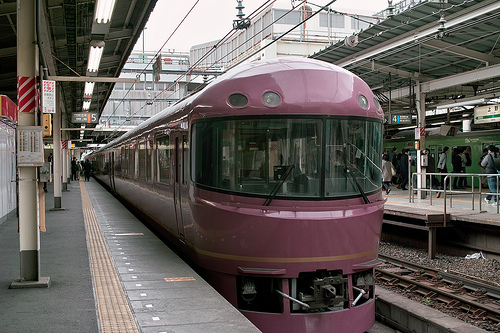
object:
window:
[147, 116, 384, 199]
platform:
[0, 156, 250, 326]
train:
[85, 56, 385, 329]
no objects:
[409, 315, 427, 325]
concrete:
[60, 174, 244, 329]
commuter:
[119, 97, 413, 298]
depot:
[29, 32, 143, 273]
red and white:
[10, 72, 50, 127]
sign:
[11, 71, 68, 122]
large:
[199, 115, 391, 216]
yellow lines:
[76, 183, 134, 331]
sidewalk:
[62, 142, 195, 329]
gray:
[146, 14, 213, 66]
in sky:
[147, 7, 194, 54]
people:
[69, 139, 103, 189]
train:
[387, 113, 498, 193]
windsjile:
[422, 143, 495, 206]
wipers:
[264, 161, 387, 214]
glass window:
[231, 140, 385, 215]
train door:
[142, 104, 214, 234]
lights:
[201, 73, 402, 136]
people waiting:
[60, 148, 119, 188]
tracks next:
[387, 225, 498, 323]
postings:
[23, 49, 59, 186]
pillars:
[47, 21, 84, 253]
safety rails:
[406, 166, 480, 216]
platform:
[382, 154, 500, 241]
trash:
[434, 233, 497, 284]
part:
[57, 233, 104, 282]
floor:
[52, 210, 80, 325]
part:
[182, 141, 285, 195]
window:
[244, 130, 387, 216]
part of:
[62, 186, 121, 286]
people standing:
[54, 118, 114, 225]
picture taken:
[7, 13, 484, 323]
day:
[165, 17, 223, 72]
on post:
[9, 33, 94, 326]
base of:
[16, 238, 56, 301]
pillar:
[16, 0, 71, 324]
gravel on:
[413, 241, 487, 285]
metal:
[407, 154, 499, 237]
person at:
[474, 138, 499, 198]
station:
[11, 11, 188, 333]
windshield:
[242, 119, 334, 205]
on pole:
[7, 49, 51, 295]